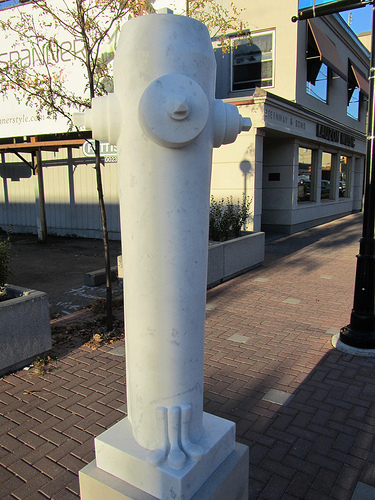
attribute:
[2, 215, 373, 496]
floor — brown, tiled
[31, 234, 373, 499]
sidewalk — brick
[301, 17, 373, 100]
awnings — out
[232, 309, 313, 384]
tile — brown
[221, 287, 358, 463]
floor — tiled, brown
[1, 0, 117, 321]
tree — dying, small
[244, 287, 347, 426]
floor — brown, tiled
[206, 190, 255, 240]
plants — green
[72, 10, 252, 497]
pillar — white, concrete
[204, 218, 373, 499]
tile — brown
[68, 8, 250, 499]
firehydrant — white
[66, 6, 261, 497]
fire hydrant — huge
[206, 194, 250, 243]
plants — leafy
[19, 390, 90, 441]
sidewalk — brick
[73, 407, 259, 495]
base — square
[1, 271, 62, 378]
planter — concrete